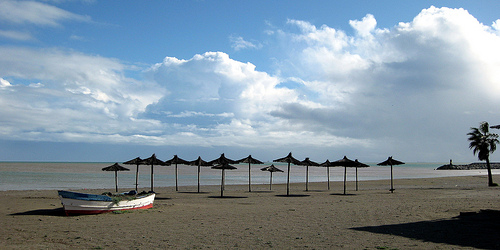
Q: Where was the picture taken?
A: On a beach.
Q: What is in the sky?
A: Clouds.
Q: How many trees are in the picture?
A: One.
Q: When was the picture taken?
A: Daytime.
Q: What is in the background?
A: Water.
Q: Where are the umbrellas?
A: On the beach.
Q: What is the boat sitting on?
A: The beach.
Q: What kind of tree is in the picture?
A: Palm tree.